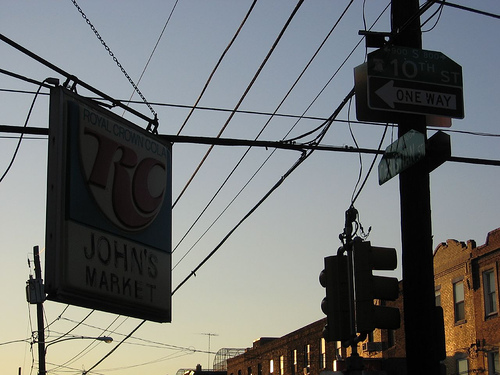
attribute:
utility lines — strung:
[0, 0, 446, 373]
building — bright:
[224, 223, 499, 373]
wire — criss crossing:
[171, 1, 255, 144]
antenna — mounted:
[200, 331, 217, 368]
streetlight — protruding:
[268, 184, 443, 351]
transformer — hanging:
[19, 244, 50, 307]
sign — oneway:
[365, 71, 467, 123]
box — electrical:
[25, 270, 51, 302]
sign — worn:
[26, 71, 180, 335]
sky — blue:
[264, 198, 315, 303]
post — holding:
[32, 244, 45, 374]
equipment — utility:
[26, 277, 47, 303]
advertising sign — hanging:
[44, 78, 176, 325]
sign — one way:
[351, 46, 471, 120]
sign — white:
[349, 35, 473, 125]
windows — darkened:
[237, 337, 344, 373]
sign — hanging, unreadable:
[46, 80, 179, 326]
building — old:
[430, 237, 477, 374]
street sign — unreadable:
[376, 127, 426, 185]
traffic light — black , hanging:
[345, 233, 404, 336]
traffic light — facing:
[317, 235, 399, 345]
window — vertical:
[479, 261, 498, 320]